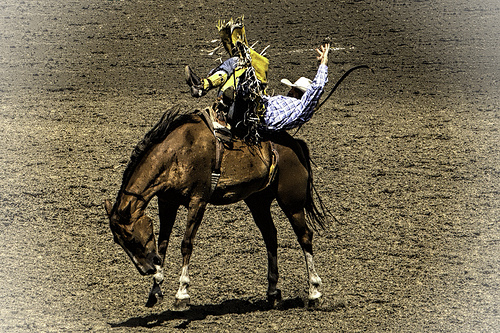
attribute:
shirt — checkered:
[265, 62, 329, 127]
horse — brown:
[101, 103, 323, 310]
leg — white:
[172, 193, 209, 310]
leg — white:
[144, 191, 185, 311]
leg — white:
[273, 194, 327, 313]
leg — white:
[242, 195, 286, 307]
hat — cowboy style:
[283, 69, 318, 90]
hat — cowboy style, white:
[281, 76, 314, 92]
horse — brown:
[102, 104, 349, 311]